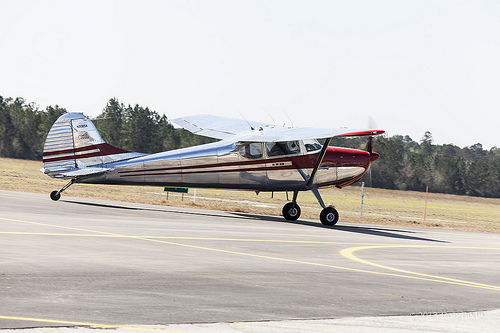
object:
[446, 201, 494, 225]
field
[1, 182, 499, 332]
runway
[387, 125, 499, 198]
trees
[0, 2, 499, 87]
sky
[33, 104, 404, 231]
airplane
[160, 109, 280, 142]
wings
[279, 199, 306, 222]
wheel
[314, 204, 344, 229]
wheel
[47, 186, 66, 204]
wheel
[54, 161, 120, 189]
tail wing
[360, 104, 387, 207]
propeller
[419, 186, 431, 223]
post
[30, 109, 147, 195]
tail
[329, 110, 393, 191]
nose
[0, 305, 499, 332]
edge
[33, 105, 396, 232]
side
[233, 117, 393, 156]
wing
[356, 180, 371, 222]
post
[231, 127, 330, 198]
cockpit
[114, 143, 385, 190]
stripes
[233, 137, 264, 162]
window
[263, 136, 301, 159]
window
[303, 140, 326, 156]
window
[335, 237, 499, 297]
circle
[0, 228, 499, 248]
line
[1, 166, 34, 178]
grass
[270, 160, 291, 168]
writing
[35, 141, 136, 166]
stripes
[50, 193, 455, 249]
shadow